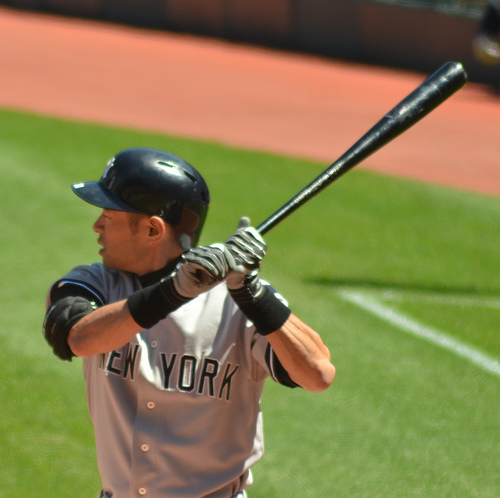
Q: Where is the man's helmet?
A: On his head.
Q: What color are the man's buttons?
A: White.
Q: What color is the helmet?
A: Black.